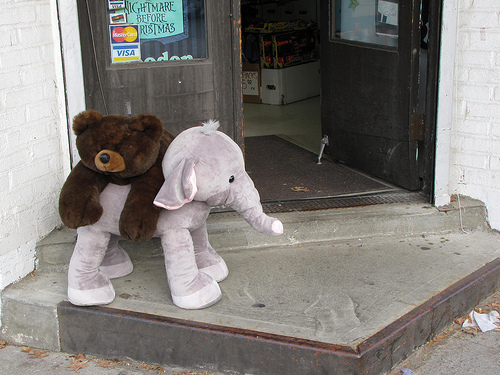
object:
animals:
[57, 109, 284, 310]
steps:
[0, 193, 499, 374]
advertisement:
[109, 0, 183, 39]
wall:
[450, 0, 499, 233]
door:
[318, 0, 421, 191]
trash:
[462, 310, 499, 333]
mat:
[243, 135, 402, 203]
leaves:
[424, 296, 500, 347]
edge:
[59, 257, 499, 375]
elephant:
[66, 119, 283, 311]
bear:
[58, 109, 175, 242]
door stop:
[316, 135, 328, 165]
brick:
[0, 0, 65, 289]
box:
[260, 61, 321, 105]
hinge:
[410, 112, 426, 141]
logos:
[108, 23, 140, 63]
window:
[105, 0, 210, 69]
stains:
[399, 234, 470, 255]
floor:
[242, 95, 411, 201]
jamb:
[254, 192, 433, 213]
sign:
[117, 49, 135, 56]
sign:
[112, 31, 136, 38]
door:
[76, 0, 242, 162]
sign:
[109, 13, 126, 24]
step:
[35, 193, 489, 272]